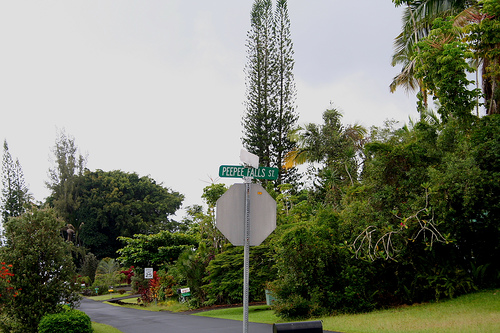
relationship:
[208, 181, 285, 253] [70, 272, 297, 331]
sign beneath street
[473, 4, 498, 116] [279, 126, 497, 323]
palm tree behind bushes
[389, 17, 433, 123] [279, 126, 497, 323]
palm tree behind bushes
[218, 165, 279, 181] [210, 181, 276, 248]
green sign above sign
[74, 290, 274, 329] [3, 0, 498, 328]
road in residential area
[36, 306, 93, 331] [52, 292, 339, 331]
green bush on side of road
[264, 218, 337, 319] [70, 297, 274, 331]
tree grows next to street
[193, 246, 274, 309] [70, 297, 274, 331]
tree grows next to street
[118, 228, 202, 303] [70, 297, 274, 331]
tree grows next to street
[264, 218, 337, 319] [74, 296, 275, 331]
tree on roadside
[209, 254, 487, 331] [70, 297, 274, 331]
grass on side of street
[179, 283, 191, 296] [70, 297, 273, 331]
mailbox on side of road